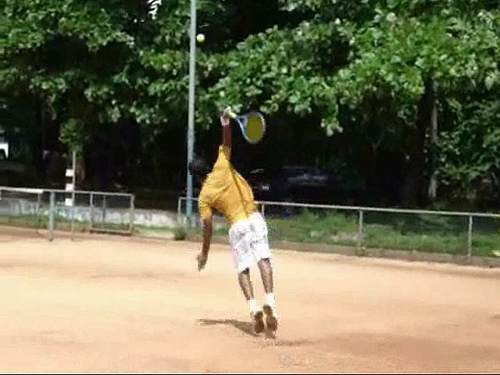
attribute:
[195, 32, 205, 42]
ball — tennis ball, yellow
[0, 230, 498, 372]
ground — brown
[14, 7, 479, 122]
trees — leafy, green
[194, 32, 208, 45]
tennis ball — green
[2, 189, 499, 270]
metal railing — gray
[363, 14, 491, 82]
leaves — green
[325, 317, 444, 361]
court — tennis court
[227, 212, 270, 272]
shorts — white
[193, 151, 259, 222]
shirt — yellow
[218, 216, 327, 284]
shorts — tennis shorts, white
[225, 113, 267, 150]
racket — tennis racket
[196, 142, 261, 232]
shirt — yellow 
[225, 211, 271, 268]
shorts — white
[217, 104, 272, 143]
racket — green